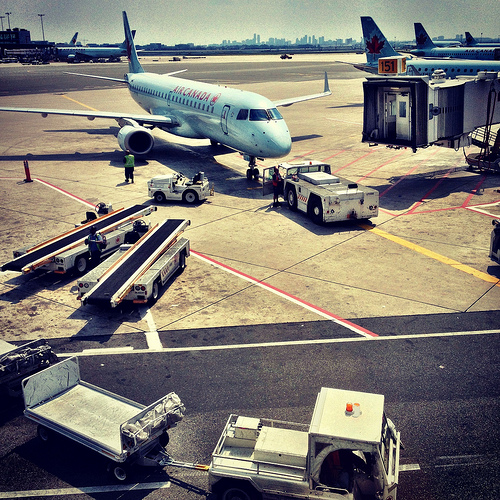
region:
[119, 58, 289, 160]
the airline is aircanada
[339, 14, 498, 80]
there are four planes on the ground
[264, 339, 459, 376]
the tarmac is grey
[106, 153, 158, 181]
the reflector is green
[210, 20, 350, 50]
the city is in the background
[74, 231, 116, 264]
the guy has a blue shirt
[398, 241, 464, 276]
the lines are yellow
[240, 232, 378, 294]
the ground is tiled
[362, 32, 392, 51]
the tail has a flower emblem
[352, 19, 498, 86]
theplanes are parked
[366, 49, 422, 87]
number 151 at gate exit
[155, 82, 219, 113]
air canada logo on air plane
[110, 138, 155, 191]
person in green vest facing away from camera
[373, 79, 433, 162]
exit door from airport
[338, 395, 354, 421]
orange safety light on top of vehicle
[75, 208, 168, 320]
luggage conveyor belts ontop of trailer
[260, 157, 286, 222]
person with orange vest exiting vehicle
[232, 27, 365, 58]
city skyline in the back of photo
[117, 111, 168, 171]
Round airplane engine on left side of picture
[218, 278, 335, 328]
red and white lines on runway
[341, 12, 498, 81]
Three airplanes parked at their gates.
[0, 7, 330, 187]
Air Canada airplane.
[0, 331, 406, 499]
Vehicle and luggage carts.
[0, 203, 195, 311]
Two belts to move luggage off of plane.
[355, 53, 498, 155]
Jetway for gate 151.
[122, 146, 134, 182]
Person in a neon safety vest.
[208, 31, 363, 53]
City skyline.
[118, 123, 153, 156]
Jet engine.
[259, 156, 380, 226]
Truck with a person standing by the open door.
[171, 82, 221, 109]
Air Canada name and logo.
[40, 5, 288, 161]
airplane parked on runway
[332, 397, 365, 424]
light on top of vehicle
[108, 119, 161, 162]
large engine on airplane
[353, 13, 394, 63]
tail on commercial airplane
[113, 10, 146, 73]
tail on commercial airplane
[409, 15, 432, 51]
tail on commercial airplane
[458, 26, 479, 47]
tail on commercial airplane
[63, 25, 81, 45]
tail on commercial airplane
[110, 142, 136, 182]
man in safety vest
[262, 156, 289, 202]
person standing by truck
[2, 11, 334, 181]
long white plane on tarmac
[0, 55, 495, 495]
gray asphalt paved tarmac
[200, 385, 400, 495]
little white vehicle pulling cart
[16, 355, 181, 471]
white luggage cart being pulled by vehicle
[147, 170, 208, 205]
small white vehicle near plane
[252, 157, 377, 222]
large white vehicle front of plane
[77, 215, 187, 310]
conveyor belt vehicle near plane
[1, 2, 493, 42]
hazy gray sky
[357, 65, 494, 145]
metal passenger ramp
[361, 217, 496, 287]
yellow painted line on tarmac